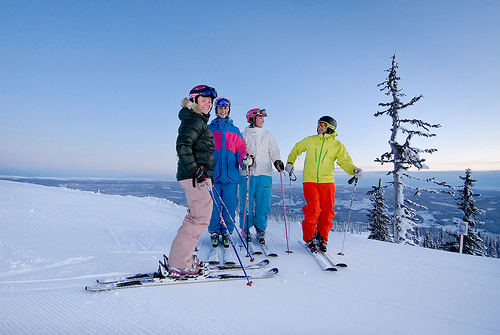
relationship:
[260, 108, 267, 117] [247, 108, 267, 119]
goggles on helmet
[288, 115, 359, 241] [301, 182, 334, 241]
man wearing pants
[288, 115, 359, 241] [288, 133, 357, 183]
man wearing jacket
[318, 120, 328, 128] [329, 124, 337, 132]
goggles have straps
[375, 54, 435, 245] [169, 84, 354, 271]
tree behind group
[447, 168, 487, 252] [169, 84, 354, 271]
tree behind group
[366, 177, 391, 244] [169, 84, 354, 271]
tree behind group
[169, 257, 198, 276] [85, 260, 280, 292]
boots attatched to ski's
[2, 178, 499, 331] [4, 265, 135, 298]
snow has marks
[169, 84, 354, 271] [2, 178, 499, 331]
group on snow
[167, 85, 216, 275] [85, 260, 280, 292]
woman on ski's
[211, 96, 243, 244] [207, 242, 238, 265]
woman on ski's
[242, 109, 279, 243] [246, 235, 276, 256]
woman on ski's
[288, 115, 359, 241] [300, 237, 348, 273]
man on ski's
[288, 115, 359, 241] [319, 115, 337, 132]
man wearing helmet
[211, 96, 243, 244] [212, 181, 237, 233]
woman wearing pants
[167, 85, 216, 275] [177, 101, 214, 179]
woman wearing jacket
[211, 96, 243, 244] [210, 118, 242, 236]
woman wearing blue